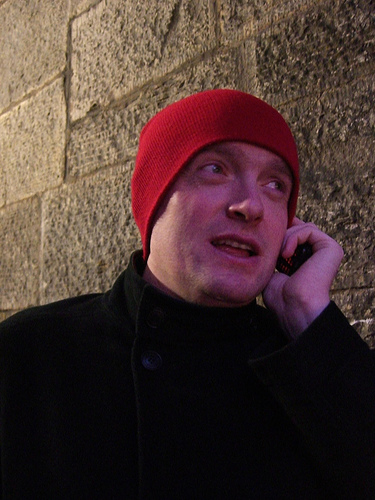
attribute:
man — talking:
[139, 88, 296, 312]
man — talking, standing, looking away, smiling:
[2, 89, 367, 499]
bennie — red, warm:
[130, 87, 297, 262]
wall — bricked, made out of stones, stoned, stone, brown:
[0, 4, 373, 331]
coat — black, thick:
[6, 251, 374, 496]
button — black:
[140, 345, 168, 372]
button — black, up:
[140, 304, 171, 338]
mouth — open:
[202, 232, 264, 266]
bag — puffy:
[200, 171, 232, 185]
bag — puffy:
[266, 186, 285, 203]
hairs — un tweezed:
[239, 151, 271, 174]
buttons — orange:
[281, 250, 298, 273]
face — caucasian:
[167, 134, 294, 298]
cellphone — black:
[274, 234, 317, 275]